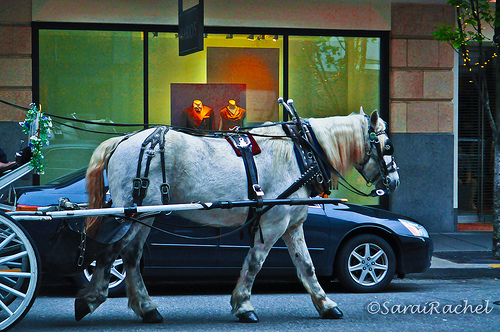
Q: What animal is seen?
A: Horse.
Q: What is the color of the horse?
A: White.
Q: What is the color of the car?
A: Black.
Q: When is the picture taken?
A: Daytime.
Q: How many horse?
A: 1.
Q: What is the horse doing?
A: Pulling cart.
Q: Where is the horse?
A: Road.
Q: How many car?
A: One.